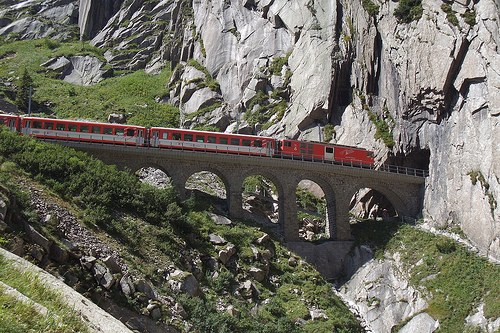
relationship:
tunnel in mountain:
[365, 126, 452, 224] [12, 2, 499, 261]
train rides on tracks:
[0, 113, 374, 169] [2, 131, 430, 191]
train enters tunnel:
[0, 113, 374, 169] [365, 126, 452, 224]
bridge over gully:
[36, 140, 429, 259] [5, 160, 497, 332]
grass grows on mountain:
[1, 0, 499, 331] [12, 2, 499, 261]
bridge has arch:
[36, 140, 429, 259] [131, 163, 175, 193]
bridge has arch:
[36, 140, 429, 259] [185, 169, 228, 206]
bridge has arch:
[36, 140, 429, 259] [240, 172, 281, 234]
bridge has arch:
[36, 140, 429, 259] [295, 178, 330, 244]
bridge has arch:
[36, 140, 429, 259] [351, 186, 395, 226]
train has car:
[0, 113, 374, 169] [20, 117, 146, 148]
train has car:
[0, 113, 374, 169] [147, 126, 277, 156]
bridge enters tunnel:
[36, 140, 429, 259] [365, 126, 452, 224]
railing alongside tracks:
[10, 127, 429, 179] [2, 131, 430, 191]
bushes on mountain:
[8, 141, 292, 332] [12, 2, 499, 261]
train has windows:
[0, 113, 374, 169] [1, 118, 334, 154]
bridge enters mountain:
[36, 140, 429, 259] [12, 2, 499, 261]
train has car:
[0, 113, 374, 169] [1, 114, 21, 133]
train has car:
[0, 113, 374, 169] [277, 139, 376, 167]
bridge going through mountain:
[36, 140, 429, 259] [12, 2, 499, 261]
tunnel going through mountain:
[365, 126, 452, 224] [12, 2, 499, 261]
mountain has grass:
[12, 2, 499, 261] [1, 0, 499, 331]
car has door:
[277, 139, 376, 167] [323, 146, 335, 161]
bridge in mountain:
[36, 140, 429, 259] [12, 2, 499, 261]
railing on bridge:
[10, 127, 429, 179] [36, 140, 429, 259]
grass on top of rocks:
[1, 0, 499, 331] [2, 2, 499, 332]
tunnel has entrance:
[365, 126, 452, 224] [378, 143, 437, 179]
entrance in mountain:
[378, 143, 437, 179] [12, 2, 499, 261]